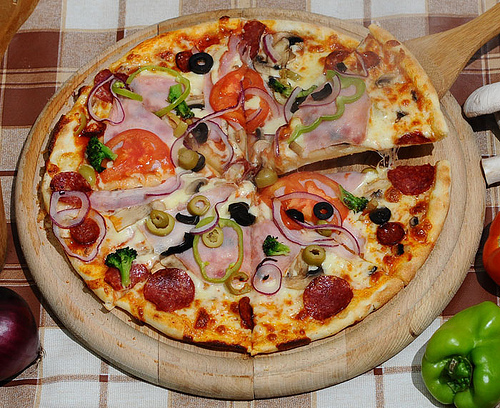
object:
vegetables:
[285, 70, 367, 144]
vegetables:
[193, 216, 244, 284]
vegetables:
[167, 83, 196, 119]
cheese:
[118, 59, 384, 294]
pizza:
[37, 15, 452, 356]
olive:
[188, 52, 215, 75]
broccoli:
[107, 247, 136, 286]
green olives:
[79, 165, 96, 186]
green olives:
[255, 168, 279, 188]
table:
[0, 1, 499, 406]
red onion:
[271, 191, 363, 256]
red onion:
[283, 87, 303, 122]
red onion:
[333, 52, 369, 78]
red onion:
[274, 123, 288, 156]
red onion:
[274, 74, 341, 158]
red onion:
[260, 33, 282, 63]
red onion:
[242, 88, 280, 124]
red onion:
[251, 263, 282, 296]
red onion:
[190, 199, 222, 235]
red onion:
[48, 189, 107, 262]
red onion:
[87, 75, 125, 124]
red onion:
[193, 117, 235, 169]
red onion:
[144, 169, 193, 196]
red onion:
[169, 87, 280, 171]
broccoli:
[339, 184, 369, 214]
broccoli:
[263, 235, 290, 256]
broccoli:
[340, 188, 369, 211]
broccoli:
[86, 136, 119, 174]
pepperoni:
[387, 164, 436, 196]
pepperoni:
[302, 275, 354, 321]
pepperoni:
[70, 219, 100, 246]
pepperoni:
[50, 171, 91, 205]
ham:
[296, 75, 370, 151]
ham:
[173, 220, 299, 283]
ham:
[218, 36, 285, 131]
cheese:
[365, 96, 397, 148]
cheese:
[320, 230, 357, 276]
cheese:
[220, 181, 274, 221]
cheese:
[162, 168, 202, 205]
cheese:
[285, 43, 327, 88]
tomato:
[96, 129, 175, 191]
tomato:
[209, 66, 272, 133]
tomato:
[262, 171, 350, 232]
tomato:
[482, 211, 500, 285]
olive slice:
[313, 201, 334, 220]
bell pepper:
[419, 299, 500, 407]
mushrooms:
[178, 148, 206, 172]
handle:
[402, 2, 500, 100]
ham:
[88, 75, 184, 209]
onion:
[0, 285, 44, 384]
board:
[15, 6, 487, 400]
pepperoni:
[142, 267, 196, 312]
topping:
[138, 52, 365, 265]